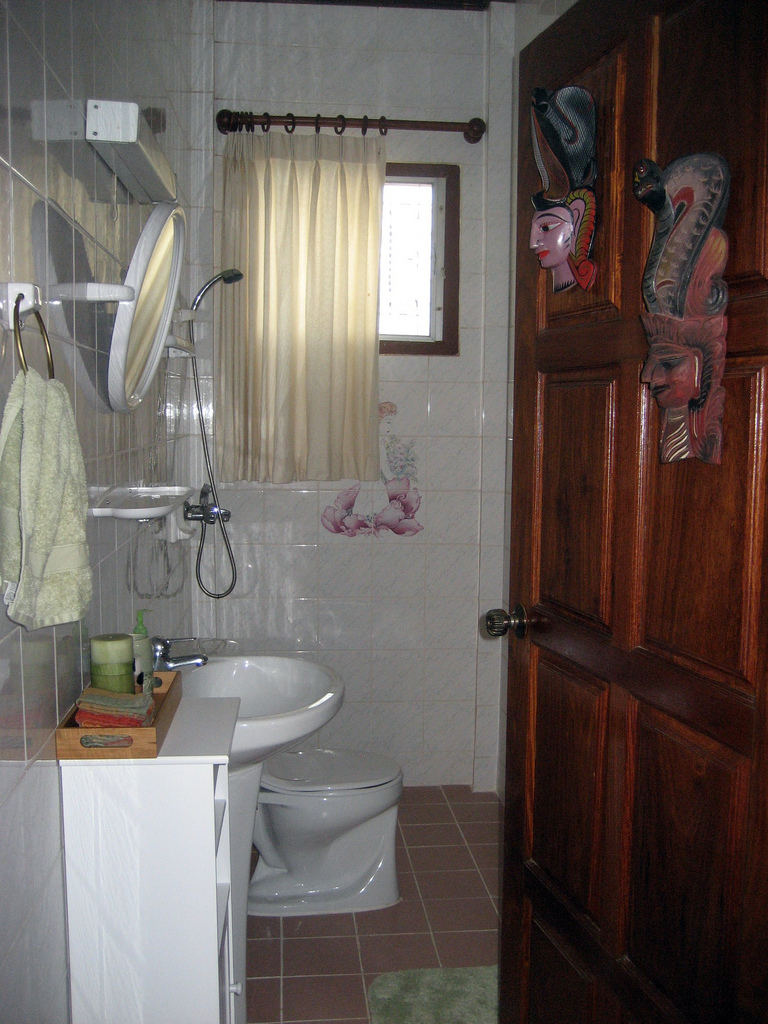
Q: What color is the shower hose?
A: Silver.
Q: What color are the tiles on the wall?
A: White.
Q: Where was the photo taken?
A: In a house.